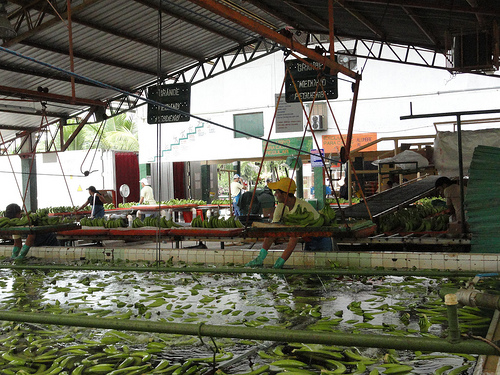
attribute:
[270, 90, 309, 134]
sign — white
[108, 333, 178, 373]
fish — green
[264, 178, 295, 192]
cap — yellow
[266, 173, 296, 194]
hat — yellow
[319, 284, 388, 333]
fish — green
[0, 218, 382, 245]
tables — side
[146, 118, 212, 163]
line — zig zag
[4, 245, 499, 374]
bananas — green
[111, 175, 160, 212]
scale — round